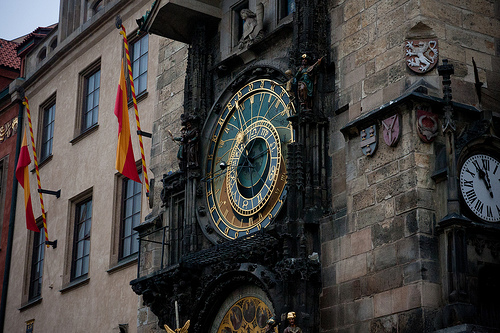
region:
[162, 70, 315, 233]
A big green clock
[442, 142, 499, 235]
A small white clock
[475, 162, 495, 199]
Hands on a small white clock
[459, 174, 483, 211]
numbers on a small white clock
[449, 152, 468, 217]
The edge of a small white clock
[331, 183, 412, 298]
A brick wall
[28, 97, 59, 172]
A window in a building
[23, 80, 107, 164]
Two windows in a building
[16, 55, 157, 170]
Three windows in a building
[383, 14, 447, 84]
A lion on a wall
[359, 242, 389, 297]
part of a wall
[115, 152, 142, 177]
part of a flag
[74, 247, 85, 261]
part of a window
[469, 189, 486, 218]
part of a roman clock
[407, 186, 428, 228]
edge of a wall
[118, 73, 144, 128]
part of a ribbon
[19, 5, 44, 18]
part of the sky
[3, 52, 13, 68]
part of a roof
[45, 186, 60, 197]
part of a holder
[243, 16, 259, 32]
part of a statue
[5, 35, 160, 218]
Two flags are seen.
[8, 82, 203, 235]
Flag is yellow and red color.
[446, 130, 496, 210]
one clock is seen.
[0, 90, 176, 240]
Flags are attached to the wall.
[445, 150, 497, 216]
Clock is white and black color.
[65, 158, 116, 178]
Building is brown color.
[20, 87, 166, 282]
Windows are in the wall.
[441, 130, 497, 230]
11.55 is the time shown.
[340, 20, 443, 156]
Four shield is seen.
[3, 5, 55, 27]
sky is blue color.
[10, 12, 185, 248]
elevated poles with yellow and red flags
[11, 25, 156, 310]
rows of windows on side of building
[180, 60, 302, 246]
gold print on round measurements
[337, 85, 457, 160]
plaques with symbols on edge of building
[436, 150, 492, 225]
white clock with black numbers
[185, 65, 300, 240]
ring on top of a larger rimmed circle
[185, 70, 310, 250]
ring off-center on circle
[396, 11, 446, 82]
stylized animal with spread claws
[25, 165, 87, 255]
dark supports holding swirled pole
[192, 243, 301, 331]
round and dark pictures under an arch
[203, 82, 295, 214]
this is a clock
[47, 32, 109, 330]
the building is cream in color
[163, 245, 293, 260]
the clock has metallic frame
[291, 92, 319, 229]
the frame is black in color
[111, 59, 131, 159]
the flag is orange and red in color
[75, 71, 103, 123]
the window is closed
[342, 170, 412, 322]
the wall is made of stones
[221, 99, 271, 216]
the clock is golden in color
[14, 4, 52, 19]
the sky is clear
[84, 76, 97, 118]
the window is clear